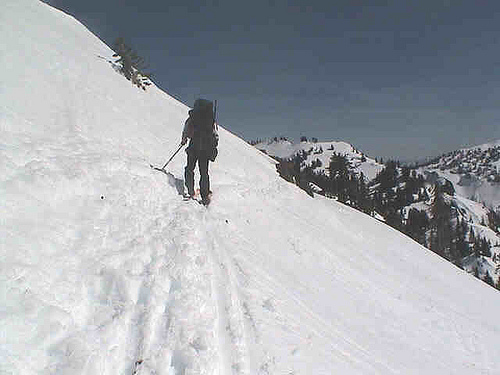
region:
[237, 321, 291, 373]
Snow covering the ground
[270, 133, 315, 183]
Snow covering the ground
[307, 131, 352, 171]
Snow covering the ground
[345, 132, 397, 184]
Snow covering the ground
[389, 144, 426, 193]
Snow covering the ground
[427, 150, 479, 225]
Snow covering the ground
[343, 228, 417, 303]
Snow covering the ground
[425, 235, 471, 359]
Snow covering the ground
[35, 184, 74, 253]
Snow covering the ground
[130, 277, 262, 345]
Snow covering the ground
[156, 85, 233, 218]
a skier walking on a hill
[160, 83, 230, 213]
man carry a backpack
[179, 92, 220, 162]
the backpack is large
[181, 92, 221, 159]
the backpack is black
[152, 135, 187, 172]
a pole on left side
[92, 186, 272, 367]
marks of skis on the snow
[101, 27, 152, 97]
a green branch on the hill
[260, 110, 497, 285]
pines on the mountain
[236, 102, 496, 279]
mountain is covered with snow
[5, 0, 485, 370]
a hill covered with snow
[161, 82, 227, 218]
solo skier on a mountain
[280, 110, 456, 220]
mountain covered with snow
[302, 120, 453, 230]
mountain covered with trees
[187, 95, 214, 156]
giant back pack on a skier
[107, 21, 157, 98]
single tree on a mountain side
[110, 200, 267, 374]
ski tracks in the snow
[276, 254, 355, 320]
white snow on the ground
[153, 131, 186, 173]
one ski pole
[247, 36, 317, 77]
overcast grey sky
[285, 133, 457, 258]
group of many ever green trees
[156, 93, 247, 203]
Man skiing up the mountain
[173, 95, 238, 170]
Man wearing a back pack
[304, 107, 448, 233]
Trees on a mountain top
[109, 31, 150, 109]
Tree in the snow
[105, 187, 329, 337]
Tracks in the snow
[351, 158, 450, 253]
Trees in the mountain top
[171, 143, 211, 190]
Man wearing black pants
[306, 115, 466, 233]
Trees in the mountain top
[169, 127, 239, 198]
Man with black pants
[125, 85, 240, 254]
the man is walking on the snow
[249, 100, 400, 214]
the mountain is covered with snow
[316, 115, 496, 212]
the mountain is covered with snow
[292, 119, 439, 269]
the mountain is covered with snow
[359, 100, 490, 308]
the mountain is covered with snow